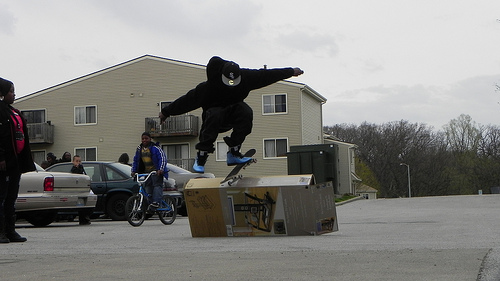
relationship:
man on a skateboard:
[160, 56, 303, 178] [209, 139, 259, 184]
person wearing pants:
[1, 73, 35, 247] [0, 147, 26, 228]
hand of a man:
[156, 107, 173, 127] [160, 56, 303, 178]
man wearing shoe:
[160, 56, 303, 178] [190, 146, 205, 175]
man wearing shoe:
[160, 56, 303, 178] [221, 141, 254, 171]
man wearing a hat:
[160, 56, 303, 178] [223, 60, 247, 83]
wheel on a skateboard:
[248, 155, 259, 165] [231, 151, 255, 190]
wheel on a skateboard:
[238, 173, 244, 178] [231, 151, 255, 190]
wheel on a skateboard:
[225, 179, 232, 189] [231, 151, 255, 190]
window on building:
[71, 143, 116, 175] [25, 52, 212, 211]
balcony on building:
[139, 110, 216, 140] [0, 51, 343, 204]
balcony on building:
[139, 110, 216, 140] [7, 23, 406, 235]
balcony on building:
[13, 119, 50, 146] [7, 23, 406, 235]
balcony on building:
[157, 151, 210, 183] [7, 23, 406, 235]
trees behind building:
[343, 97, 489, 213] [7, 48, 354, 198]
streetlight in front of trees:
[400, 153, 412, 191] [364, 120, 484, 190]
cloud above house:
[102, 2, 262, 44] [9, 55, 324, 174]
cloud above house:
[102, 2, 262, 44] [8, 34, 367, 211]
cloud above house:
[102, 2, 262, 44] [1, 52, 358, 197]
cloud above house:
[102, 2, 262, 44] [0, 48, 333, 208]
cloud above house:
[102, 2, 262, 44] [1, 52, 325, 220]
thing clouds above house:
[158, 51, 340, 242] [0, 48, 333, 208]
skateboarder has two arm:
[153, 55, 303, 172] [244, 67, 304, 85]